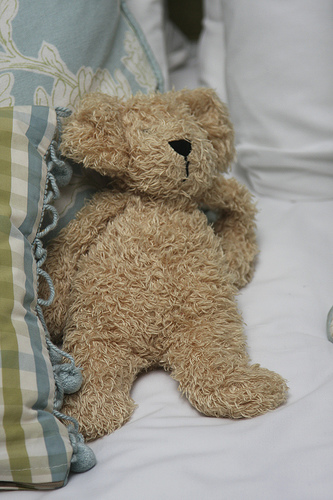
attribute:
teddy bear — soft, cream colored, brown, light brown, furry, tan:
[38, 87, 291, 444]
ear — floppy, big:
[59, 87, 134, 177]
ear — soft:
[174, 85, 236, 171]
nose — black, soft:
[171, 139, 193, 156]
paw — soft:
[185, 366, 292, 423]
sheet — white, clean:
[55, 2, 331, 498]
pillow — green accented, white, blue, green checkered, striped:
[3, 103, 86, 494]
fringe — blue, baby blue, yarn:
[30, 108, 93, 479]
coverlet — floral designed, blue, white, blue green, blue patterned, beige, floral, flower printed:
[2, 2, 173, 133]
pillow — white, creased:
[194, 2, 332, 204]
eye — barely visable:
[135, 126, 153, 139]